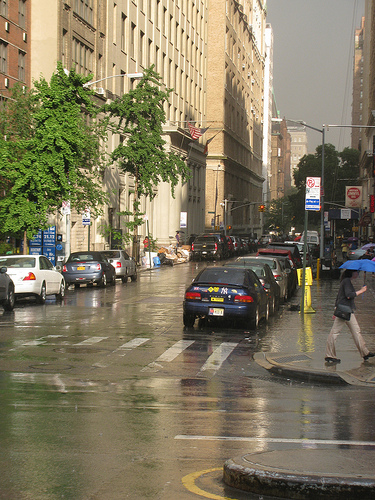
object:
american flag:
[187, 121, 203, 140]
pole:
[320, 126, 325, 259]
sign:
[305, 176, 321, 212]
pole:
[301, 210, 308, 318]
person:
[325, 269, 375, 363]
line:
[196, 341, 239, 377]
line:
[138, 338, 195, 372]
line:
[92, 338, 152, 367]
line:
[72, 336, 109, 346]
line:
[21, 335, 63, 346]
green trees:
[5, 72, 97, 269]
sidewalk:
[137, 255, 156, 271]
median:
[223, 446, 375, 497]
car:
[62, 252, 116, 285]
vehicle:
[7, 254, 66, 303]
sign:
[296, 266, 315, 314]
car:
[260, 262, 281, 313]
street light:
[127, 72, 144, 78]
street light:
[260, 205, 264, 209]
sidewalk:
[264, 239, 374, 383]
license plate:
[208, 307, 224, 316]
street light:
[271, 117, 283, 123]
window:
[16, 47, 27, 85]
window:
[72, 40, 76, 60]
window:
[130, 23, 135, 59]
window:
[174, 22, 179, 51]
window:
[230, 34, 236, 55]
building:
[0, 0, 31, 154]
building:
[57, 0, 108, 254]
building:
[109, 2, 205, 248]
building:
[206, 3, 263, 223]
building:
[287, 119, 310, 189]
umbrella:
[339, 258, 374, 272]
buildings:
[350, 1, 373, 179]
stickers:
[214, 286, 219, 292]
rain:
[75, 295, 109, 312]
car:
[183, 267, 271, 329]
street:
[3, 266, 373, 402]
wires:
[337, 5, 358, 147]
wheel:
[59, 280, 65, 299]